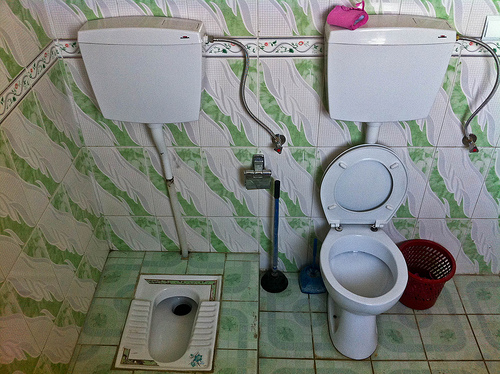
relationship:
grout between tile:
[308, 308, 318, 358] [256, 309, 316, 361]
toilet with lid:
[317, 136, 410, 362] [319, 140, 409, 231]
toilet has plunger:
[317, 136, 410, 362] [259, 175, 291, 293]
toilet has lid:
[317, 136, 410, 362] [319, 140, 409, 231]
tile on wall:
[51, 3, 494, 257] [49, 1, 499, 274]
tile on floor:
[108, 250, 497, 371] [260, 267, 499, 373]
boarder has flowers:
[59, 37, 499, 58] [265, 41, 319, 56]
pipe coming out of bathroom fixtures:
[206, 29, 286, 153] [75, 16, 201, 125]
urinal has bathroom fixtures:
[114, 271, 226, 372] [75, 16, 201, 125]